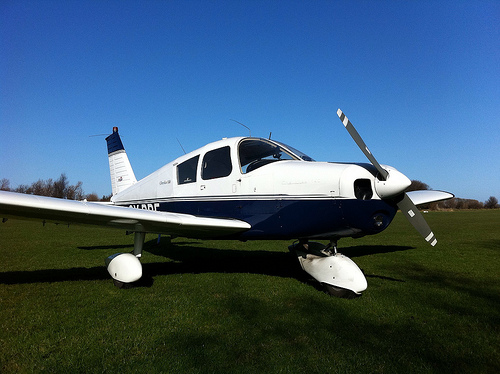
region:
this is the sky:
[224, 31, 364, 111]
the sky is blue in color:
[208, 10, 312, 96]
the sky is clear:
[62, 17, 256, 62]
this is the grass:
[16, 303, 113, 350]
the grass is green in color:
[11, 282, 119, 365]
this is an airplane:
[7, 117, 453, 290]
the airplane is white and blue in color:
[274, 162, 319, 228]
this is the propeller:
[338, 95, 467, 263]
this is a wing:
[0, 177, 257, 240]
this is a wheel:
[326, 281, 344, 296]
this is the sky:
[125, 20, 470, 110]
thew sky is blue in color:
[230, 2, 321, 68]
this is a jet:
[161, 141, 401, 261]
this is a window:
[200, 150, 245, 165]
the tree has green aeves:
[54, 181, 66, 188]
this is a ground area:
[145, 275, 236, 340]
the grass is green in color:
[165, 295, 230, 340]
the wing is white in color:
[22, 191, 52, 203]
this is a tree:
[42, 176, 77, 196]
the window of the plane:
[197, 145, 233, 180]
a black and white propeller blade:
[326, 100, 386, 180]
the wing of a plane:
[0, 185, 255, 240]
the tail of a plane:
[100, 120, 136, 196]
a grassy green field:
[0, 205, 496, 370]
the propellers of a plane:
[333, 104, 441, 251]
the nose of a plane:
[373, 158, 412, 201]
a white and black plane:
[0, 105, 458, 300]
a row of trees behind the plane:
[1, 167, 108, 204]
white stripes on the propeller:
[421, 223, 441, 248]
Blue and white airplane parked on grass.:
[8, 105, 461, 303]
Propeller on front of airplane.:
[333, 106, 447, 259]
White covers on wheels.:
[108, 250, 382, 302]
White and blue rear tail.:
[91, 121, 148, 200]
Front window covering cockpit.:
[235, 132, 317, 176]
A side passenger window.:
[171, 151, 207, 189]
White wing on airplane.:
[3, 182, 251, 249]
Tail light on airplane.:
[103, 123, 126, 140]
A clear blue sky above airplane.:
[133, 23, 462, 100]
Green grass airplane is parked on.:
[76, 302, 443, 370]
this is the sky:
[170, 28, 307, 118]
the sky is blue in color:
[249, 16, 293, 42]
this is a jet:
[143, 150, 386, 268]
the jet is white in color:
[283, 172, 327, 187]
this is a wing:
[8, 186, 138, 226]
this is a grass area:
[162, 250, 263, 355]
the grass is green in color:
[203, 291, 259, 369]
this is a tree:
[31, 179, 75, 191]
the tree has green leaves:
[53, 179, 63, 189]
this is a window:
[205, 152, 230, 168]